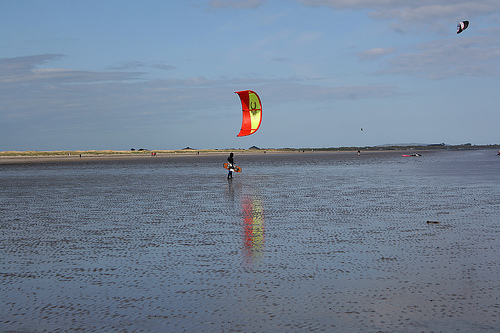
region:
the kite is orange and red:
[214, 88, 298, 162]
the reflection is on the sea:
[226, 181, 293, 249]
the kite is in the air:
[438, 7, 491, 54]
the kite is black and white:
[455, 15, 488, 53]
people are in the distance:
[20, 143, 367, 159]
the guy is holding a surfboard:
[216, 151, 251, 194]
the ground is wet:
[10, 155, 486, 330]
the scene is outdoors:
[0, 5, 480, 315]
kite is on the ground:
[398, 143, 435, 170]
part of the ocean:
[293, 260, 311, 282]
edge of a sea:
[169, 233, 201, 244]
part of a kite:
[248, 123, 257, 131]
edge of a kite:
[238, 114, 244, 126]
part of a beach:
[116, 153, 139, 167]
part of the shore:
[331, 223, 358, 289]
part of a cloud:
[374, 60, 389, 79]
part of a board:
[221, 161, 236, 173]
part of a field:
[92, 145, 113, 156]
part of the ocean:
[233, 307, 244, 331]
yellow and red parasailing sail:
[225, 83, 265, 146]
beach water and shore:
[28, 124, 422, 176]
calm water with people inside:
[145, 54, 437, 280]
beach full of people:
[48, 135, 356, 165]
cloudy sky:
[35, 14, 427, 131]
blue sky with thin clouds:
[48, 30, 213, 133]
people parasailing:
[315, 10, 473, 190]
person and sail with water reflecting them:
[227, 78, 287, 263]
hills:
[125, 138, 422, 153]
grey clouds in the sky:
[10, 64, 185, 138]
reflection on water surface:
[236, 197, 274, 255]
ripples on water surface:
[221, 186, 406, 247]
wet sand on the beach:
[0, 143, 499, 331]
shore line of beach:
[1, 134, 488, 176]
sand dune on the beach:
[183, 140, 197, 154]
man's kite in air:
[226, 87, 265, 139]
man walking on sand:
[221, 150, 241, 185]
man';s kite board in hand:
[216, 162, 245, 174]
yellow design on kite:
[243, 90, 265, 136]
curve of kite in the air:
[250, 88, 265, 153]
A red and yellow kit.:
[232, 70, 267, 141]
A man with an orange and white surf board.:
[222, 151, 243, 181]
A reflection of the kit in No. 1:
[239, 191, 271, 260]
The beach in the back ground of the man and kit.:
[4, 145, 255, 155]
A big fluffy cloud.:
[346, 40, 393, 67]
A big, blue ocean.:
[3, 160, 225, 325]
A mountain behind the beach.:
[247, 144, 262, 152]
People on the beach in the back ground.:
[247, 143, 391, 156]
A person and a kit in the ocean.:
[212, 85, 269, 181]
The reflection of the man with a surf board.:
[220, 177, 241, 208]